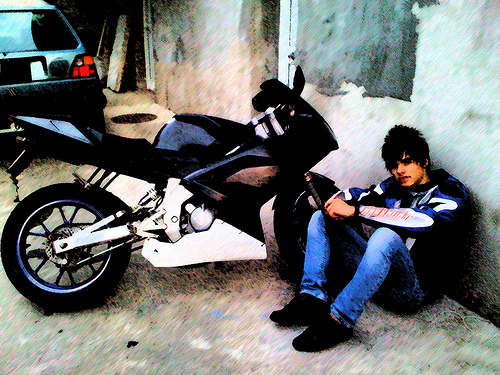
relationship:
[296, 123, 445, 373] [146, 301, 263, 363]
boy on ground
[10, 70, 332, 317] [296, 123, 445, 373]
motorcycle beside boy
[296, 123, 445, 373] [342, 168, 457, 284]
boy wearing jacket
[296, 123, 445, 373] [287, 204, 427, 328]
boy wearing jeans